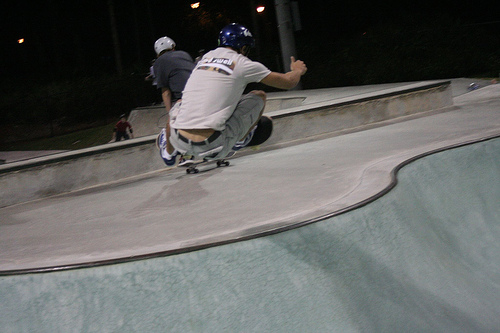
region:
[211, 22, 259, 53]
the helmet is blue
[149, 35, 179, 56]
the helmet is white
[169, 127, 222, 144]
the belt is black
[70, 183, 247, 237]
the pavement is gray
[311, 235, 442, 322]
the ramp is gray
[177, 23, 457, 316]
man above the ramp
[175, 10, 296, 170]
man is doing trick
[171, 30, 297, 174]
man above the skateboard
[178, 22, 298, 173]
man is a skateboarder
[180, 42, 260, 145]
the shirt is white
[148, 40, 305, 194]
two men are sitting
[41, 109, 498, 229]
a beautiful view of wood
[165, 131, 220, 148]
a black belt of a person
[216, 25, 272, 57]
a person wearing blue cap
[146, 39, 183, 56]
white cap on the head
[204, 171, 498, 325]
a black clean road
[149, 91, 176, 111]
hand of the person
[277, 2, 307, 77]
a small pillar on road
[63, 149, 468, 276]
a beautiful curve on road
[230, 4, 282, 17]
a small street light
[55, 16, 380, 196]
skateboarders performing tricks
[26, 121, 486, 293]
curves on flat gray surface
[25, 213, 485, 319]
grey textured surface of slope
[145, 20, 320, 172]
rider low on skateboard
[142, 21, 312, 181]
skateboarder approaching elevated step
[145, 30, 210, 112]
skateboarder in dark shirt in front of another skateboarder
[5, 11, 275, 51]
lights shining in dark background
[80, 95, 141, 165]
skateboarder at bottom on slope in back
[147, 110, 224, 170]
foot sticking out in front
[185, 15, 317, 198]
skateboarder giving thumbs up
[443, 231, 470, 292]
The color of this jump is a very light blue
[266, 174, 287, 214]
The color of this ramp is a very light grey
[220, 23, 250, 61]
This man is wearing a blue helmet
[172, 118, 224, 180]
This man is wearing a brown belt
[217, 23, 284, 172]
This man is practicing skateboarding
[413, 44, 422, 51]
There is a dark black color in the sky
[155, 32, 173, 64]
This man is wearing a silver helmet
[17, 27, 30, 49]
There is a bright light that is overhead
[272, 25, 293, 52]
There is a steel pole that is visible in the distance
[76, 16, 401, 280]
This photo is taken place at night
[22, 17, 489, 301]
men skating at park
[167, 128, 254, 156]
back end of man skating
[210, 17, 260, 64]
blue helmet on man's head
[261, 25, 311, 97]
arm of man outstretched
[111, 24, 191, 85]
white helmet of man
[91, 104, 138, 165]
man in background of skate park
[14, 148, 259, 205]
skate board beneath man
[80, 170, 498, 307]
bowl at skatepark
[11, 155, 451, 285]
grinding lip on top of bowl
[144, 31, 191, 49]
grey helmet on man